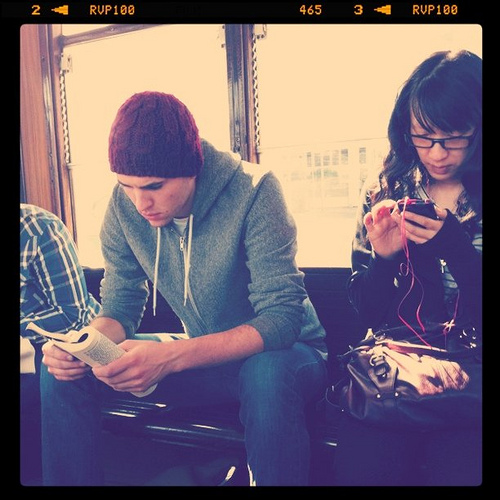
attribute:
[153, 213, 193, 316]
strings — white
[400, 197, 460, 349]
earbud cord — pink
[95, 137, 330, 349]
shirt — white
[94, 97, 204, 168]
hat — knit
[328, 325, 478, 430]
purse — black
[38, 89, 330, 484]
man — young, sitting, reading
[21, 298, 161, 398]
book — folded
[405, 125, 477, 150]
glasses — black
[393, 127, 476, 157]
glasses — black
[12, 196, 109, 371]
shirt — plaid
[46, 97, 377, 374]
hoodie — gray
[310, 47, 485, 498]
passenger — sitting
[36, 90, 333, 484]
passenger — sitting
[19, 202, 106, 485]
passenger — sitting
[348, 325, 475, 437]
purse — Leather 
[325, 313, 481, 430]
purse — brown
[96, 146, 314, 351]
jacket — grey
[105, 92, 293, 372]
guy — reading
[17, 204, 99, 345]
shirt — plaid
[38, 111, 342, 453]
man — reading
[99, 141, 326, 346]
sweatshirt — hooded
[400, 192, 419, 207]
headphone — pink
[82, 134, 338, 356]
hoodie — gray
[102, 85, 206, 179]
hat — red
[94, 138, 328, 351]
hoodie — gray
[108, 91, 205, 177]
hat — burgundy, wool